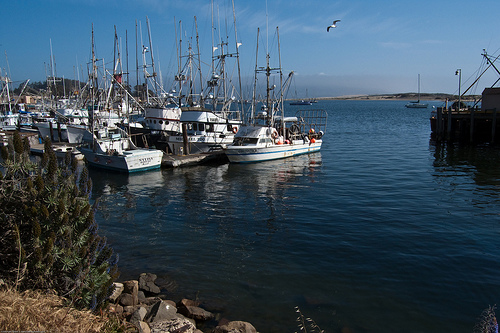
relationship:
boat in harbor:
[221, 24, 328, 164] [15, 93, 498, 309]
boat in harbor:
[169, 0, 242, 158] [15, 93, 498, 309]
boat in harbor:
[70, 25, 166, 175] [15, 93, 498, 309]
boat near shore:
[222, 26, 328, 163] [0, 147, 287, 330]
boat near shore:
[169, 0, 244, 158] [0, 147, 287, 330]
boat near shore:
[70, 43, 166, 174] [0, 147, 287, 330]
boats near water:
[66, 45, 377, 215] [168, 110, 495, 235]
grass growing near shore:
[0, 286, 103, 333] [398, 74, 485, 181]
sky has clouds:
[282, 45, 473, 92] [313, 39, 360, 74]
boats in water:
[406, 93, 419, 110] [327, 111, 430, 262]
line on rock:
[164, 299, 172, 311] [148, 297, 180, 324]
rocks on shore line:
[102, 268, 255, 331] [2, 282, 256, 330]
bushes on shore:
[5, 177, 130, 292] [102, 245, 219, 332]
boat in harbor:
[222, 26, 328, 163] [134, 123, 494, 325]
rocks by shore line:
[102, 268, 255, 331] [85, 237, 296, 327]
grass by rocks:
[0, 286, 103, 333] [102, 268, 255, 331]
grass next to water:
[0, 286, 103, 333] [325, 185, 405, 257]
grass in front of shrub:
[15, 286, 102, 331] [5, 158, 98, 286]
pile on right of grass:
[93, 268, 260, 330] [0, 286, 103, 333]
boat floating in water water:
[221, 24, 328, 164] [16, 98, 499, 331]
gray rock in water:
[176, 297, 223, 322] [16, 98, 499, 331]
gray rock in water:
[137, 271, 180, 293] [16, 98, 499, 331]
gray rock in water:
[213, 320, 259, 332] [16, 98, 499, 331]